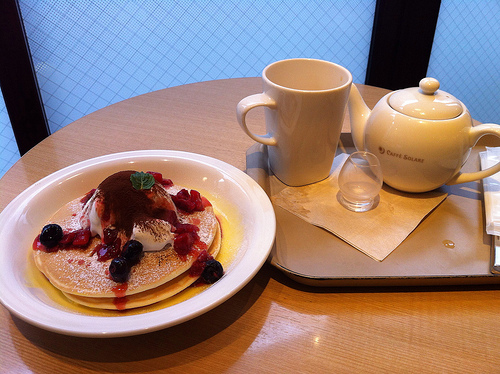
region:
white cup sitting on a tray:
[236, 59, 353, 189]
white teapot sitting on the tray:
[346, 76, 498, 193]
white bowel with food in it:
[0, 149, 277, 373]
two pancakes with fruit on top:
[33, 171, 223, 311]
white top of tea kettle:
[386, 77, 463, 121]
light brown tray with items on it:
[261, 129, 498, 290]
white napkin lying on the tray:
[268, 153, 447, 263]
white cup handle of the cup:
[233, 92, 278, 148]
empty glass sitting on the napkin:
[340, 153, 382, 211]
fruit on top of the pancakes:
[103, 169, 163, 223]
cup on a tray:
[230, 61, 343, 174]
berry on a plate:
[193, 245, 223, 277]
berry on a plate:
[100, 252, 131, 277]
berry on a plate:
[120, 237, 151, 263]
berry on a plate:
[37, 215, 67, 252]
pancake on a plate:
[82, 275, 128, 300]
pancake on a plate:
[121, 298, 151, 313]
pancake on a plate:
[28, 158, 230, 299]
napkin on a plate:
[320, 217, 415, 267]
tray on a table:
[290, 265, 430, 297]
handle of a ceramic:
[223, 79, 277, 150]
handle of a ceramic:
[460, 113, 490, 198]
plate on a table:
[0, 142, 281, 352]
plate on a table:
[225, 92, 495, 307]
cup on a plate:
[335, 142, 385, 222]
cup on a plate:
[255, 45, 360, 185]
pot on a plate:
[332, 55, 485, 200]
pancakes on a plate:
[26, 170, 242, 320]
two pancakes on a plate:
[15, 152, 236, 319]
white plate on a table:
[0, 105, 288, 340]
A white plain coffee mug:
[238, 58, 352, 188]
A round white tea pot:
[347, 78, 499, 195]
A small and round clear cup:
[336, 150, 383, 211]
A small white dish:
[1, 148, 276, 339]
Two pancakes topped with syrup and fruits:
[33, 168, 223, 310]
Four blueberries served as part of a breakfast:
[41, 223, 223, 282]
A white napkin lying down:
[271, 152, 448, 259]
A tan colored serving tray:
[246, 131, 499, 288]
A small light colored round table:
[1, 76, 498, 372]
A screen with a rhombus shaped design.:
[0, 0, 499, 179]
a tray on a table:
[245, 129, 498, 285]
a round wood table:
[0, 77, 498, 372]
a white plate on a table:
[0, 148, 276, 338]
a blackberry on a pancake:
[40, 221, 62, 243]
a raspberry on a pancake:
[173, 187, 202, 208]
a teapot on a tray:
[346, 77, 498, 193]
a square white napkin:
[272, 150, 447, 262]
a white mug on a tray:
[237, 57, 350, 187]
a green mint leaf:
[130, 168, 153, 192]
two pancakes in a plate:
[32, 182, 219, 309]